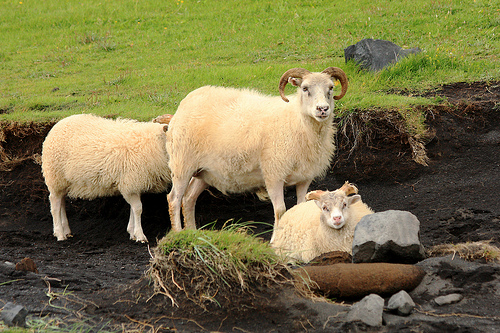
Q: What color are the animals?
A: White.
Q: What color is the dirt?
A: Black.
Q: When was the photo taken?
A: Daytime.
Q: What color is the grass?
A: Green.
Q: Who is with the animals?
A: No one.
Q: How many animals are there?
A: Three.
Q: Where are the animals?
A: By a field.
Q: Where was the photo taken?
A: In a ditch.